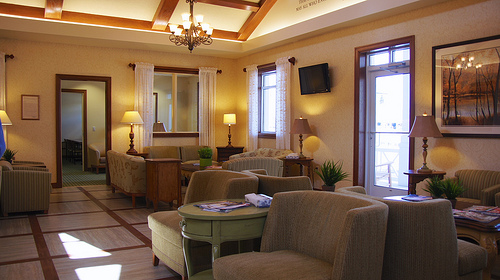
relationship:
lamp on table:
[117, 109, 145, 156] [121, 151, 148, 159]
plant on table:
[423, 173, 445, 208] [386, 185, 496, 279]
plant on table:
[441, 174, 461, 209] [177, 159, 223, 190]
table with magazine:
[179, 191, 276, 278] [193, 199, 251, 214]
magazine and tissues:
[193, 199, 251, 214] [243, 186, 274, 208]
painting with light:
[431, 34, 498, 139] [457, 53, 482, 70]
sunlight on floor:
[56, 228, 121, 278] [0, 182, 185, 278]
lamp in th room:
[290, 116, 312, 158] [1, 1, 491, 278]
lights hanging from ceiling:
[160, 14, 217, 55] [231, 6, 331, 38]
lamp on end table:
[408, 111, 441, 171] [403, 169, 445, 196]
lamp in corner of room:
[117, 109, 145, 156] [1, 1, 491, 278]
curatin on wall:
[133, 61, 154, 153] [3, 30, 235, 190]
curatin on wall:
[196, 65, 216, 165] [3, 30, 235, 190]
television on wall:
[289, 53, 335, 97] [333, 102, 349, 148]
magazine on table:
[194, 195, 259, 215] [179, 191, 276, 278]